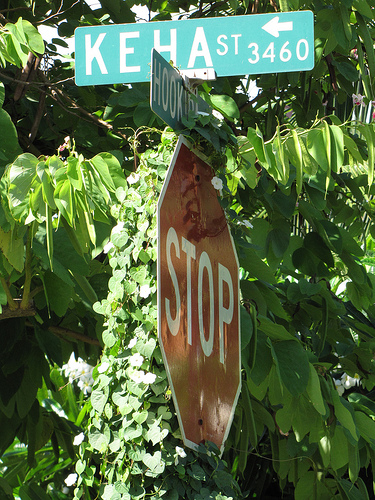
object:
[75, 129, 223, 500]
ivy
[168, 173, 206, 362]
graffiti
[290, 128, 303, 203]
pod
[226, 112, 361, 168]
limb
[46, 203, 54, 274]
pods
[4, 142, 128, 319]
group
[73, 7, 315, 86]
street sign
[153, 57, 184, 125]
hook st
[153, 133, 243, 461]
stop sign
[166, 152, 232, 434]
reflection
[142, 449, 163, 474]
leaves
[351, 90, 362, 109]
flowers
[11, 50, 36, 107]
sticks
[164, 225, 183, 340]
s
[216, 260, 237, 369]
p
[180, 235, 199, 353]
t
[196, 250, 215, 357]
o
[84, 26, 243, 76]
keha st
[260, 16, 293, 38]
arrow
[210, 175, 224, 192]
flower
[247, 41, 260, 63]
numbers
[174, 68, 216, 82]
bracket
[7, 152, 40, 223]
leaves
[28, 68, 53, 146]
branches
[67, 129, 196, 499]
vine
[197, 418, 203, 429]
screw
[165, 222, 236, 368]
stop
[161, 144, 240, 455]
red background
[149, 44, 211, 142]
street sign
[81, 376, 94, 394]
flowers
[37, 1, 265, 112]
sky